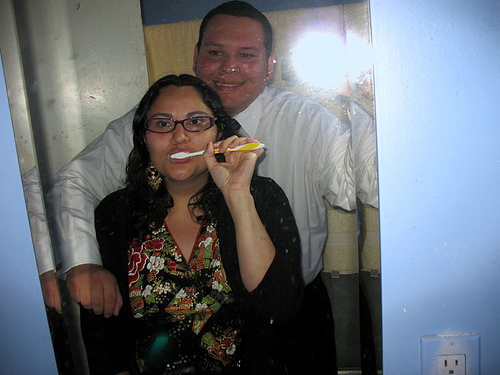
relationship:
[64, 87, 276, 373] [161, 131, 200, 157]
lady with teeth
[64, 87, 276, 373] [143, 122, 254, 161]
lady with toothbrush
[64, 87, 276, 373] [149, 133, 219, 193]
lady with mouth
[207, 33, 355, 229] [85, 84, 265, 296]
man behind lady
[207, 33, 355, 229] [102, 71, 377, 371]
man behind lady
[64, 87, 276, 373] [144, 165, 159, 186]
lady wearing earrings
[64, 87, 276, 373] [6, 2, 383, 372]
lady in front mirror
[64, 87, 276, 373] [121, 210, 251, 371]
lady wearing blouse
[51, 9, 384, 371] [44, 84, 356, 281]
man wearing shirt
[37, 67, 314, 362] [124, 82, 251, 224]
woman with hair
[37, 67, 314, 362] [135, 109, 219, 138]
woman wearing glasses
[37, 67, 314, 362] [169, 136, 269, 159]
woman using toothbrush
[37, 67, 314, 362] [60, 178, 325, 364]
woman wearing sweater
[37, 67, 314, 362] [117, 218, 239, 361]
woman wearing shirt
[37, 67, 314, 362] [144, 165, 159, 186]
woman with earrings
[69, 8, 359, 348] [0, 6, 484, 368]
camera in picture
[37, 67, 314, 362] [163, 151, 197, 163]
woman brushing teeth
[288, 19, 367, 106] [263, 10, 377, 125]
flash from camera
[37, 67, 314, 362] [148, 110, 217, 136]
woman wearing glasses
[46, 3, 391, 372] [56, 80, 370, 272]
he wearing shirt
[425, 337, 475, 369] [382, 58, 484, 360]
outlet on wall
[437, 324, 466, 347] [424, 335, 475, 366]
paint on outlet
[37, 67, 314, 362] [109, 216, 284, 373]
woman wearing dress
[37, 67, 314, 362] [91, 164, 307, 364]
woman wearing jacket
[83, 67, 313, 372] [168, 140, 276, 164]
girl has toothbrush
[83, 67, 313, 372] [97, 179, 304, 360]
girl wearing sweater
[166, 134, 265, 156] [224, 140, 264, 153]
toothbrush has stripe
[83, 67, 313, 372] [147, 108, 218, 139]
girl wearing glasses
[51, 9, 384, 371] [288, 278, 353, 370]
man wearing pants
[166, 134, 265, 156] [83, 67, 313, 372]
toothbrush with girl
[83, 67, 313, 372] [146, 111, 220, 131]
girl wearing glasses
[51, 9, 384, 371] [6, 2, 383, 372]
man in mirror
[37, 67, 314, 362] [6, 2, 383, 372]
woman in mirror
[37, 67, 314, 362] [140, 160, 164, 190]
woman wearing earrings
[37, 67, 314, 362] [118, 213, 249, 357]
woman wearing shirt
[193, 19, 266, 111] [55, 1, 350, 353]
face of man